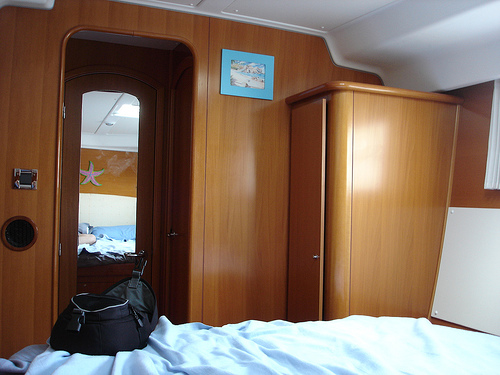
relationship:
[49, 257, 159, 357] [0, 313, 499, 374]
bag on bed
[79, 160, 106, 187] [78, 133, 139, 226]
star sign on wall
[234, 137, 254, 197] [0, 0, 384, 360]
light shining on wall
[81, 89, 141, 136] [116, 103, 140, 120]
ceiling has light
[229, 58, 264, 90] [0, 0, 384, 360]
photo on wall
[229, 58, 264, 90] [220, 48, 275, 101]
photo has frame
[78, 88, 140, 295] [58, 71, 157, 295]
mirror on door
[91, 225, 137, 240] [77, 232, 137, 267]
pillow on bed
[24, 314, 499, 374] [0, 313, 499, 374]
bedcover on bed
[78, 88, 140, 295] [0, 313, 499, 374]
mirror across from bed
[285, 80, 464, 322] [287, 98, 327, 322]
closet with door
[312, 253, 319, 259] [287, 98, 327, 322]
knob on door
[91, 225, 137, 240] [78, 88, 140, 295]
pillow in mirror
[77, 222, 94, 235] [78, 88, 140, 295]
pillow in mirror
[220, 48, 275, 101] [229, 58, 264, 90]
frame around photo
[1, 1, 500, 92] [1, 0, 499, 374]
ceiling above bedroom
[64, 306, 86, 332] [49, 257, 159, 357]
strap on side of bag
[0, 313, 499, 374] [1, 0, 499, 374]
bed in bedroom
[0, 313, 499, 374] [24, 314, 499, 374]
bed covered by bedcover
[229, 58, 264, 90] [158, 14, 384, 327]
photo on closet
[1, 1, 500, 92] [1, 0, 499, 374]
ceiling of bedroom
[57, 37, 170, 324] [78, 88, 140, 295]
closet has mirror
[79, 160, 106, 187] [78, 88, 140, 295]
star sign reflected in mirror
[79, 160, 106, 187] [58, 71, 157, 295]
star sign on door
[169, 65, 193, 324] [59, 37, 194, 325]
door in corner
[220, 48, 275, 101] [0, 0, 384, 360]
frame hung on wall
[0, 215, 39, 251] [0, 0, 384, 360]
circle on side of wall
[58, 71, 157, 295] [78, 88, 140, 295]
door has mirror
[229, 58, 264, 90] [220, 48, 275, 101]
photo in frame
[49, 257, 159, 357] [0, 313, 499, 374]
bag sitting on bed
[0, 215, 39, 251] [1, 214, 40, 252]
circle with trim